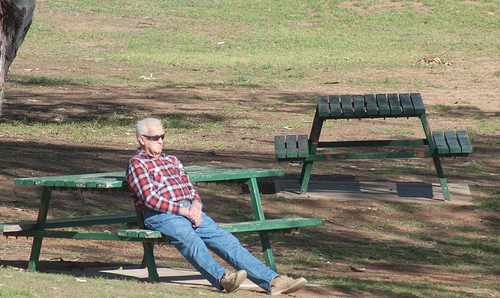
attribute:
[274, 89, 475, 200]
picnic table — green, wooden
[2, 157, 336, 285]
picnic table — wooden, green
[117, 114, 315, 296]
man — old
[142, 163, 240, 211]
shirt — white, red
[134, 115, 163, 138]
hair — white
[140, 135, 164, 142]
sunglasses — black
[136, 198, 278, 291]
jeans — blue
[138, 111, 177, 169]
hair — white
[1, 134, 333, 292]
bench — public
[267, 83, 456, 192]
table — picnic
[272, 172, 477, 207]
concerete slab — concrete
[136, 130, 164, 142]
sunglasses — dark, black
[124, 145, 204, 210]
plaid shirt — red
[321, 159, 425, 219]
shadows — under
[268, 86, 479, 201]
picnic bench — green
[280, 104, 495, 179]
picnic table — green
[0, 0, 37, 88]
tree — large, not shown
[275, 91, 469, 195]
table — empty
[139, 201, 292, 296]
jeans — blue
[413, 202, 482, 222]
grass — missing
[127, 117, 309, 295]
man — older, old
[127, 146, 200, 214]
shirt — plaid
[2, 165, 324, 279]
bench — green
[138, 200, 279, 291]
pants — blue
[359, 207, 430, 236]
dirt — brown